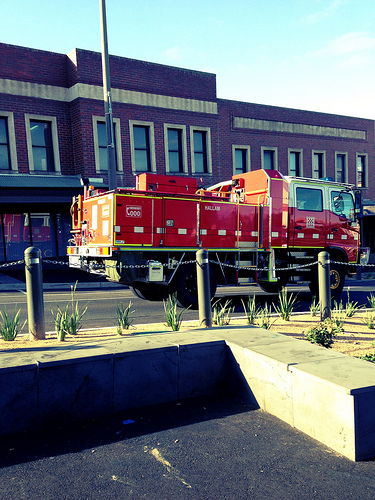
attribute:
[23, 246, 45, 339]
pole — metal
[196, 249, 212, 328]
pole — metal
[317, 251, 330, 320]
pole — metal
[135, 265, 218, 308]
wheels — back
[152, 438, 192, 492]
markings — tan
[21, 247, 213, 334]
poles — metal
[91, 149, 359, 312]
truck — large, red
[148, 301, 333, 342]
plants — little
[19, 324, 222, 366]
ledge — concrete